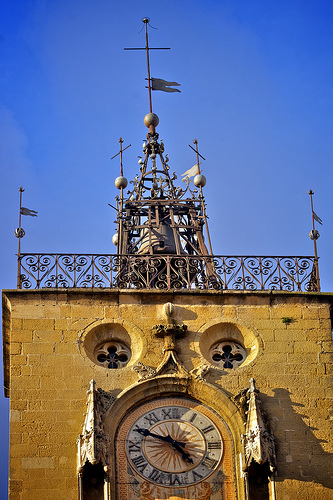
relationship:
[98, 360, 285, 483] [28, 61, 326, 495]
clock on building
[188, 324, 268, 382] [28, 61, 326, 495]
cross on building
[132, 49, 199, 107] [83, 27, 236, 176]
flag on top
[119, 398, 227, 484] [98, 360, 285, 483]
roman numerals on clock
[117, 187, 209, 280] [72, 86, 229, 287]
bell on top of tower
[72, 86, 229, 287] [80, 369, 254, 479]
tower with clock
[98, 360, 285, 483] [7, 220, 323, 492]
clock on building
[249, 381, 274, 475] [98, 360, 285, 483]
shape near clock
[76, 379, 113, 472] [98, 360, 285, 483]
shape near clock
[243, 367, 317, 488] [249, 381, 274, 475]
shadow of shape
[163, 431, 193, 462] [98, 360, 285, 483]
hand on clock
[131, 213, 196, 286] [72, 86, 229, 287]
bell on tower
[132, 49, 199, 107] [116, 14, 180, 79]
flag on cross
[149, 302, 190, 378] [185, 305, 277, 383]
decoration on window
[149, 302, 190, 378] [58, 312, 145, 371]
decoration on window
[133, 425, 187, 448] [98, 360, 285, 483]
hand on clock